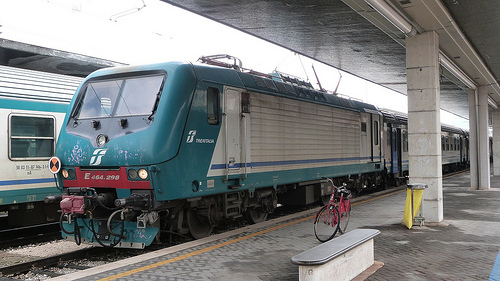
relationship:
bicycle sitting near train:
[301, 173, 362, 245] [45, 47, 490, 279]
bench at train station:
[288, 226, 386, 280] [2, 1, 481, 279]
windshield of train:
[73, 68, 165, 121] [40, 51, 484, 255]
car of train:
[46, 49, 384, 255] [40, 51, 484, 255]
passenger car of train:
[377, 105, 467, 188] [40, 51, 484, 255]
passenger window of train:
[402, 130, 410, 154] [56, 55, 466, 242]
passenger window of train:
[442, 131, 449, 151] [43, 61, 477, 247]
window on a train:
[11, 116, 54, 159] [3, 66, 83, 230]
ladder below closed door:
[218, 172, 253, 222] [215, 80, 262, 193]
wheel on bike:
[305, 205, 350, 245] [298, 172, 426, 274]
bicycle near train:
[310, 176, 353, 244] [43, 61, 477, 247]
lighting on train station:
[379, 29, 449, 73] [289, 28, 460, 204]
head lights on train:
[136, 168, 149, 181] [45, 54, 493, 249]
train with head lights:
[45, 54, 493, 249] [136, 168, 149, 181]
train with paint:
[45, 54, 493, 249] [75, 171, 127, 182]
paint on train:
[75, 171, 127, 182] [45, 54, 493, 249]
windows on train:
[71, 75, 124, 120] [27, 40, 403, 231]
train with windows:
[27, 40, 403, 231] [71, 75, 124, 120]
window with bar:
[77, 64, 166, 124] [110, 76, 126, 122]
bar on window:
[110, 76, 126, 122] [77, 64, 166, 124]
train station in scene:
[2, 1, 481, 279] [5, 0, 487, 279]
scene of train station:
[5, 0, 487, 279] [2, 1, 481, 279]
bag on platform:
[401, 182, 428, 230] [409, 232, 473, 279]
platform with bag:
[409, 232, 473, 279] [401, 182, 428, 230]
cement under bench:
[395, 257, 469, 278] [288, 226, 386, 280]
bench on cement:
[288, 226, 386, 280] [395, 257, 469, 278]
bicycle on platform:
[310, 176, 353, 244] [43, 0, 499, 281]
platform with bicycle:
[43, 0, 499, 281] [310, 176, 353, 244]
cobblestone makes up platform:
[187, 260, 217, 276] [43, 0, 499, 281]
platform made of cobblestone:
[43, 0, 499, 281] [187, 260, 217, 276]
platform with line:
[43, 0, 499, 281] [159, 251, 210, 261]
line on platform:
[159, 251, 210, 261] [43, 0, 499, 281]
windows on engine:
[74, 66, 167, 129] [46, 140, 166, 248]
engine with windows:
[46, 140, 166, 248] [74, 66, 167, 129]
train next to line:
[45, 54, 493, 249] [93, 169, 467, 280]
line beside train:
[93, 169, 467, 280] [45, 54, 493, 249]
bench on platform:
[294, 220, 395, 279] [43, 0, 499, 281]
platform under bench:
[43, 0, 499, 281] [294, 220, 395, 279]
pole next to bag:
[404, 189, 421, 221] [402, 190, 411, 225]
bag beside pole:
[402, 190, 411, 225] [404, 189, 421, 221]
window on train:
[6, 108, 57, 158] [0, 59, 53, 229]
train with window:
[0, 59, 53, 229] [6, 108, 57, 158]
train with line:
[45, 54, 493, 249] [213, 154, 380, 172]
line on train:
[213, 154, 380, 172] [45, 54, 493, 249]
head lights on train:
[49, 160, 164, 189] [45, 54, 493, 249]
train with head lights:
[45, 54, 493, 249] [49, 160, 164, 189]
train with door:
[45, 54, 493, 249] [366, 103, 387, 163]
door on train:
[366, 103, 387, 163] [45, 54, 493, 249]